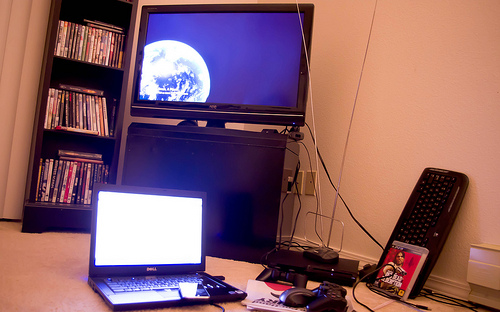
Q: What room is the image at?
A: It is at the living room.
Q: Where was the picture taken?
A: It was taken at the living room.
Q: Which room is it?
A: It is a living room.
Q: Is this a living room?
A: Yes, it is a living room.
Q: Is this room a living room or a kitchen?
A: It is a living room.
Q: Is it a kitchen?
A: No, it is a living room.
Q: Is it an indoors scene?
A: Yes, it is indoors.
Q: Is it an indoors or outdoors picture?
A: It is indoors.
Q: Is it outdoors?
A: No, it is indoors.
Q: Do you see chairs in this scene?
A: No, there are no chairs.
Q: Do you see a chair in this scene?
A: No, there are no chairs.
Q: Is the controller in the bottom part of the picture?
A: Yes, the controller is in the bottom of the image.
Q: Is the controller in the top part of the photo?
A: No, the controller is in the bottom of the image.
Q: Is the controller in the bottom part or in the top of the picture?
A: The controller is in the bottom of the image.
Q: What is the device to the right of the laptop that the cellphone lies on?
A: The device is a controller.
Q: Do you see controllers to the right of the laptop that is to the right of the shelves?
A: Yes, there is a controller to the right of the laptop.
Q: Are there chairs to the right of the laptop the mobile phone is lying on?
A: No, there is a controller to the right of the laptop computer.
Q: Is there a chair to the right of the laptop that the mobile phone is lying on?
A: No, there is a controller to the right of the laptop computer.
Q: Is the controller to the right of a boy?
A: No, the controller is to the right of the laptop.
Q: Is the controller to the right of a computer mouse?
A: Yes, the controller is to the right of a computer mouse.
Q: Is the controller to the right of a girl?
A: No, the controller is to the right of a computer mouse.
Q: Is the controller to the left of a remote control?
A: No, the controller is to the right of a remote control.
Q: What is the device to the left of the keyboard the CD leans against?
A: The device is a controller.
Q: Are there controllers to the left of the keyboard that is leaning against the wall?
A: Yes, there is a controller to the left of the keyboard.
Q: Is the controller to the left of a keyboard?
A: Yes, the controller is to the left of a keyboard.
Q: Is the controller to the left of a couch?
A: No, the controller is to the left of a keyboard.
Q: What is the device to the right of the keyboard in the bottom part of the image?
A: The device is a controller.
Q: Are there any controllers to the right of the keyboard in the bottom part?
A: Yes, there is a controller to the right of the keyboard.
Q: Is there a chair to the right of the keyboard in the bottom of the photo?
A: No, there is a controller to the right of the keyboard.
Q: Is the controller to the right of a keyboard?
A: Yes, the controller is to the right of a keyboard.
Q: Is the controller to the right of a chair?
A: No, the controller is to the right of a keyboard.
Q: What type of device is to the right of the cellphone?
A: The device is a controller.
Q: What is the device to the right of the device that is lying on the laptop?
A: The device is a controller.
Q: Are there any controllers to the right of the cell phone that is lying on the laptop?
A: Yes, there is a controller to the right of the cell phone.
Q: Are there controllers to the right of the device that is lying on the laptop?
A: Yes, there is a controller to the right of the cell phone.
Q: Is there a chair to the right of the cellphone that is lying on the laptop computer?
A: No, there is a controller to the right of the cellphone.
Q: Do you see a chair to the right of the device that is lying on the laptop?
A: No, there is a controller to the right of the cellphone.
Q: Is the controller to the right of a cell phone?
A: Yes, the controller is to the right of a cell phone.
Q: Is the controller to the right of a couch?
A: No, the controller is to the right of a cell phone.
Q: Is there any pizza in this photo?
A: Yes, there is a pizza.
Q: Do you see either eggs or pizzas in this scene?
A: Yes, there is a pizza.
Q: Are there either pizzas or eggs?
A: Yes, there is a pizza.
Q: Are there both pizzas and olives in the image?
A: No, there is a pizza but no olives.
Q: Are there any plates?
A: No, there are no plates.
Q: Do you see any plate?
A: No, there are no plates.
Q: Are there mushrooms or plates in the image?
A: No, there are no plates or mushrooms.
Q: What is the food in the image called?
A: The food is a pizza.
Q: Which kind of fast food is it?
A: The food is a pizza.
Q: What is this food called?
A: This is a pizza.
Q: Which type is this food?
A: This is a pizza.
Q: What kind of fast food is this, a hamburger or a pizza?
A: This is a pizza.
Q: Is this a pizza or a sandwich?
A: This is a pizza.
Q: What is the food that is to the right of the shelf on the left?
A: The food is a pizza.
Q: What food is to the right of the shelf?
A: The food is a pizza.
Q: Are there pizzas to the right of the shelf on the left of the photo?
A: Yes, there is a pizza to the right of the shelf.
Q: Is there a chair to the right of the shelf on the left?
A: No, there is a pizza to the right of the shelf.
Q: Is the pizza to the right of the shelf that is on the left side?
A: Yes, the pizza is to the right of the shelf.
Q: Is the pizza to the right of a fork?
A: No, the pizza is to the right of the shelf.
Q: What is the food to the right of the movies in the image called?
A: The food is a pizza.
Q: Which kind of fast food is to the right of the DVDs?
A: The food is a pizza.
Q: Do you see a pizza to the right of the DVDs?
A: Yes, there is a pizza to the right of the DVDs.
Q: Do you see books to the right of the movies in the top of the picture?
A: No, there is a pizza to the right of the movies.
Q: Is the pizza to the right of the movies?
A: Yes, the pizza is to the right of the movies.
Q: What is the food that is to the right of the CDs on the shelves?
A: The food is a pizza.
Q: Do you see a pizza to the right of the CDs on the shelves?
A: Yes, there is a pizza to the right of the CDs.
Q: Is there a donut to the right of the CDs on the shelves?
A: No, there is a pizza to the right of the CDs.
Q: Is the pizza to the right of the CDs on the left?
A: Yes, the pizza is to the right of the CDs.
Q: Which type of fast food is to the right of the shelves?
A: The food is a pizza.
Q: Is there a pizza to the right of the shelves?
A: Yes, there is a pizza to the right of the shelves.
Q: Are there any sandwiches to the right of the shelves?
A: No, there is a pizza to the right of the shelves.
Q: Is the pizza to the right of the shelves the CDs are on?
A: Yes, the pizza is to the right of the shelves.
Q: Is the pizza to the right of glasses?
A: No, the pizza is to the right of the shelves.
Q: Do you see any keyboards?
A: Yes, there is a keyboard.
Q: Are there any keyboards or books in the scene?
A: Yes, there is a keyboard.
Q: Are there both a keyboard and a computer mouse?
A: Yes, there are both a keyboard and a computer mouse.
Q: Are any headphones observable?
A: No, there are no headphones.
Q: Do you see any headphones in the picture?
A: No, there are no headphones.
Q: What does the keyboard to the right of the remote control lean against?
A: The keyboard leans against the wall.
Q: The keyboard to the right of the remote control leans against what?
A: The keyboard leans against the wall.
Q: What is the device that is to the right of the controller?
A: The device is a keyboard.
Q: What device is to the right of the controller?
A: The device is a keyboard.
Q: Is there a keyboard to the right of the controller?
A: Yes, there is a keyboard to the right of the controller.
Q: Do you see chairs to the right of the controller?
A: No, there is a keyboard to the right of the controller.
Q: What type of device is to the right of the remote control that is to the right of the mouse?
A: The device is a keyboard.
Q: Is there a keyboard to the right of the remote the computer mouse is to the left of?
A: Yes, there is a keyboard to the right of the remote control.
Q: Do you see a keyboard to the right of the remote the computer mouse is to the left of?
A: Yes, there is a keyboard to the right of the remote control.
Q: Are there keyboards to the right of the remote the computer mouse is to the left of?
A: Yes, there is a keyboard to the right of the remote control.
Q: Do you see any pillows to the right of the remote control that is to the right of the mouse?
A: No, there is a keyboard to the right of the remote.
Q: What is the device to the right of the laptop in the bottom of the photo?
A: The device is a keyboard.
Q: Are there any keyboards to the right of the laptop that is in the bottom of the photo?
A: Yes, there is a keyboard to the right of the laptop.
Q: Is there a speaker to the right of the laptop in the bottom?
A: No, there is a keyboard to the right of the laptop computer.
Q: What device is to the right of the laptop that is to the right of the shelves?
A: The device is a keyboard.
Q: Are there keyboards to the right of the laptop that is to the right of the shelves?
A: Yes, there is a keyboard to the right of the laptop.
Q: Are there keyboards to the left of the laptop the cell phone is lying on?
A: No, the keyboard is to the right of the laptop.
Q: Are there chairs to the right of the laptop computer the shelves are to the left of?
A: No, there is a keyboard to the right of the laptop.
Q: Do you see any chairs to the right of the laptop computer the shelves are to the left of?
A: No, there is a keyboard to the right of the laptop.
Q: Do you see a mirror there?
A: No, there are no mirrors.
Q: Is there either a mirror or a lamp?
A: No, there are no mirrors or lamps.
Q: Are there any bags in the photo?
A: No, there are no bags.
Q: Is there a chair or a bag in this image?
A: No, there are no bags or chairs.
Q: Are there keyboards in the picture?
A: Yes, there is a keyboard.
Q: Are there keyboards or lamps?
A: Yes, there is a keyboard.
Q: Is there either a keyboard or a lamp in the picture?
A: Yes, there is a keyboard.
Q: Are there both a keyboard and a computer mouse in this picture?
A: Yes, there are both a keyboard and a computer mouse.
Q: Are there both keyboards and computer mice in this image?
A: Yes, there are both a keyboard and a computer mouse.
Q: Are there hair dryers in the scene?
A: No, there are no hair dryers.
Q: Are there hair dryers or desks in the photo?
A: No, there are no hair dryers or desks.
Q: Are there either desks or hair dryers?
A: No, there are no hair dryers or desks.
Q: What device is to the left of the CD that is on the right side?
A: The device is a keyboard.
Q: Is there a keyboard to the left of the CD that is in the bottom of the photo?
A: Yes, there is a keyboard to the left of the CD.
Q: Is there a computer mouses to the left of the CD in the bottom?
A: No, there is a keyboard to the left of the CD.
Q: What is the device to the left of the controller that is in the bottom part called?
A: The device is a keyboard.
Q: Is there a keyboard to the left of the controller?
A: Yes, there is a keyboard to the left of the controller.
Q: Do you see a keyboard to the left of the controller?
A: Yes, there is a keyboard to the left of the controller.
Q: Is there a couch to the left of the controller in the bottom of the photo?
A: No, there is a keyboard to the left of the controller.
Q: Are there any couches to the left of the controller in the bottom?
A: No, there is a keyboard to the left of the controller.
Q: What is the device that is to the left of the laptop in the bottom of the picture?
A: The device is a keyboard.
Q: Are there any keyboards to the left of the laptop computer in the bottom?
A: Yes, there is a keyboard to the left of the laptop computer.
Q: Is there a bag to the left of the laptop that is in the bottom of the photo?
A: No, there is a keyboard to the left of the laptop.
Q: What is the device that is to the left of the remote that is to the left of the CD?
A: The device is a keyboard.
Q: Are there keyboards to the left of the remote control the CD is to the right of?
A: Yes, there is a keyboard to the left of the remote control.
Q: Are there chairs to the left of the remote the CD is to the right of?
A: No, there is a keyboard to the left of the remote.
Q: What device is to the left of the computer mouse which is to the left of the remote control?
A: The device is a keyboard.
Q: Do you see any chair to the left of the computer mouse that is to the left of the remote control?
A: No, there is a keyboard to the left of the mouse.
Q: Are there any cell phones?
A: Yes, there is a cell phone.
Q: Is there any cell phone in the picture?
A: Yes, there is a cell phone.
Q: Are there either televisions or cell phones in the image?
A: Yes, there is a cell phone.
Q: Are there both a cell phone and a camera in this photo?
A: No, there is a cell phone but no cameras.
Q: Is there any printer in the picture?
A: No, there are no printers.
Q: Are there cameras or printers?
A: No, there are no printers or cameras.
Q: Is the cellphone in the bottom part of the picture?
A: Yes, the cellphone is in the bottom of the image.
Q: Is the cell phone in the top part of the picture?
A: No, the cell phone is in the bottom of the image.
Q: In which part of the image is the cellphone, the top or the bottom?
A: The cellphone is in the bottom of the image.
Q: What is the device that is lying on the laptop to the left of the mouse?
A: The device is a cell phone.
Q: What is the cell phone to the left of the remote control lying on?
A: The mobile phone is lying on the laptop.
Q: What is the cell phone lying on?
A: The mobile phone is lying on the laptop.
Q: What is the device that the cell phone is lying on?
A: The device is a laptop.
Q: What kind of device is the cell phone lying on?
A: The cell phone is lying on the laptop.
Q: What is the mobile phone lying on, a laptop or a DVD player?
A: The mobile phone is lying on a laptop.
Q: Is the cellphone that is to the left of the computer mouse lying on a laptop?
A: Yes, the cell phone is lying on a laptop.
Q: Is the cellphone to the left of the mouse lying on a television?
A: No, the cell phone is lying on a laptop.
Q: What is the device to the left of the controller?
A: The device is a cell phone.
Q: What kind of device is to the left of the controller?
A: The device is a cell phone.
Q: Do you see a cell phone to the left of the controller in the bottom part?
A: Yes, there is a cell phone to the left of the controller.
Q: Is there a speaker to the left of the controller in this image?
A: No, there is a cell phone to the left of the controller.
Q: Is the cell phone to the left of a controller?
A: Yes, the cell phone is to the left of a controller.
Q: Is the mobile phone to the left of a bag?
A: No, the mobile phone is to the left of a controller.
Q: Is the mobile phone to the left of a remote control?
A: Yes, the mobile phone is to the left of a remote control.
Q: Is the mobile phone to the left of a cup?
A: No, the mobile phone is to the left of a remote control.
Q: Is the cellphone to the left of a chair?
A: No, the cellphone is to the left of the mouse.